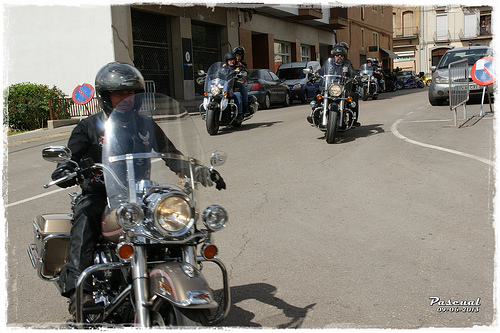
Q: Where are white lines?
A: On the pavement.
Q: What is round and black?
A: Tires.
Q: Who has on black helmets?
A: Cops, who are riding on motorcycles.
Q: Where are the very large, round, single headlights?
A: On the motorcycles.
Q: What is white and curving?
A: A line on the street.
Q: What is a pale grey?
A: The road.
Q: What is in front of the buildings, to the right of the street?
A: A green shrub and a blue and red sign.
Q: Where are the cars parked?
A: On the left and right side of the road.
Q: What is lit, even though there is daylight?
A: The headlights on the bikes.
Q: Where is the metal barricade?
A: Beside a blue and red sign, on the right side of the road.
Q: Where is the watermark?
A: In the bottom, right corner.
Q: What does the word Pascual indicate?
A: The picture's photographer, or the studio in which it was developed.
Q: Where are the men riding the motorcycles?
A: Street.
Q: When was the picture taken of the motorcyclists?
A: Saturday afternoon.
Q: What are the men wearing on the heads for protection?
A: Helmets.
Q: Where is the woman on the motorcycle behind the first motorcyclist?
A: Behind a man.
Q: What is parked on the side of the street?
A: Automobiles.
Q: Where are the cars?
A: Parked beside the street.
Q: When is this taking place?
A: Daytime.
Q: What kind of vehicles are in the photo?
A: Motorcycles.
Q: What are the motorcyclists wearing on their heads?
A: Helmets.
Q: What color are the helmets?
A: Black.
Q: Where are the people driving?
A: Street.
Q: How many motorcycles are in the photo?
A: Four.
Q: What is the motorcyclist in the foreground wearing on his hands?
A: Gloves.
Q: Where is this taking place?
A: On a street.